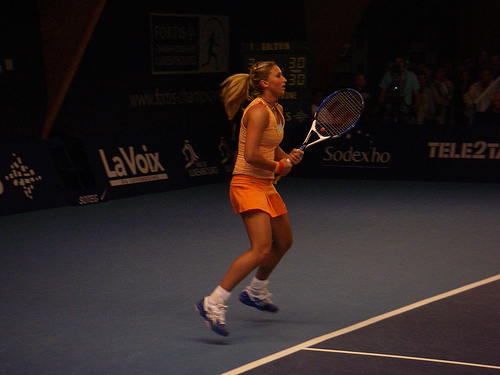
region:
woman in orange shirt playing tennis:
[194, 55, 367, 341]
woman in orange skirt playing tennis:
[192, 58, 377, 345]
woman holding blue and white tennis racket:
[186, 56, 377, 344]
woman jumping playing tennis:
[190, 53, 370, 351]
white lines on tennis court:
[300, 289, 442, 356]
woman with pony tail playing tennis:
[196, 54, 369, 340]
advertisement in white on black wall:
[91, 137, 181, 198]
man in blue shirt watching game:
[377, 52, 427, 129]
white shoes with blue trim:
[235, 274, 288, 318]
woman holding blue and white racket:
[197, 48, 372, 183]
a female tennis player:
[192, 59, 366, 336]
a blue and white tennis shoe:
[194, 294, 231, 340]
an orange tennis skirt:
[228, 174, 288, 218]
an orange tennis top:
[232, 95, 287, 179]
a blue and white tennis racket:
[295, 89, 362, 152]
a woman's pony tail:
[218, 69, 250, 121]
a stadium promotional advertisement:
[59, 137, 186, 209]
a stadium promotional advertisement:
[0, 140, 54, 205]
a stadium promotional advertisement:
[298, 131, 402, 177]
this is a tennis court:
[48, 46, 366, 264]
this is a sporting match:
[85, 35, 316, 310]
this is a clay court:
[73, 237, 223, 352]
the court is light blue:
[83, 220, 203, 345]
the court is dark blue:
[401, 320, 496, 361]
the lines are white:
[290, 306, 429, 373]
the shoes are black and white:
[181, 273, 296, 353]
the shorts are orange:
[195, 166, 304, 247]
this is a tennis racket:
[277, 87, 389, 166]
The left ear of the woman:
[258, 79, 275, 89]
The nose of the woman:
[282, 74, 291, 84]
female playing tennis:
[192, 59, 368, 337]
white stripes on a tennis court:
[221, 275, 498, 374]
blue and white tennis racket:
[275, 86, 363, 183]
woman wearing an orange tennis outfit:
[197, 57, 297, 337]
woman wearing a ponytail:
[217, 58, 289, 124]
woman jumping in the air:
[189, 58, 367, 340]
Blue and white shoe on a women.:
[193, 288, 235, 338]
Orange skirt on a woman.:
[221, 172, 293, 219]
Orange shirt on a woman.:
[228, 93, 291, 178]